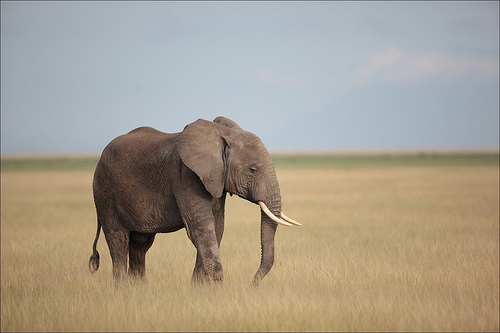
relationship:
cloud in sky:
[0, 0, 496, 157] [0, 0, 498, 150]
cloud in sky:
[357, 45, 496, 103] [2, 12, 319, 96]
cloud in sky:
[0, 0, 496, 157] [74, 13, 436, 120]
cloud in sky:
[0, 0, 496, 157] [84, 31, 420, 130]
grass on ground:
[0, 164, 500, 333] [371, 168, 436, 247]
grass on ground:
[0, 164, 500, 333] [322, 187, 484, 329]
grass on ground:
[0, 164, 500, 333] [300, 194, 469, 289]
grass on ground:
[0, 164, 500, 333] [320, 173, 450, 290]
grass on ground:
[0, 164, 500, 333] [328, 226, 459, 308]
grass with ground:
[0, 164, 500, 333] [305, 200, 475, 318]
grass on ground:
[332, 182, 454, 219] [304, 180, 447, 303]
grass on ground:
[0, 164, 500, 333] [326, 187, 459, 297]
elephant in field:
[88, 110, 306, 287] [0, 77, 473, 313]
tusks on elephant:
[258, 202, 302, 227] [82, 110, 305, 287]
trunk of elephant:
[249, 175, 281, 286] [82, 110, 305, 287]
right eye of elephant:
[248, 160, 258, 171] [82, 110, 305, 287]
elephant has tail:
[82, 110, 305, 287] [86, 195, 106, 274]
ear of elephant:
[177, 118, 228, 200] [82, 110, 305, 287]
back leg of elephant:
[102, 226, 129, 278] [90, 117, 301, 289]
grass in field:
[0, 164, 500, 333] [6, 148, 495, 329]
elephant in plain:
[82, 110, 305, 287] [0, 151, 500, 333]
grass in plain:
[0, 164, 500, 333] [7, 148, 495, 328]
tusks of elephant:
[258, 202, 302, 227] [66, 91, 298, 312]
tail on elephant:
[90, 219, 100, 273] [65, 69, 347, 299]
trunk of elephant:
[249, 175, 281, 286] [86, 113, 279, 288]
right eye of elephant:
[248, 160, 258, 171] [88, 97, 281, 292]